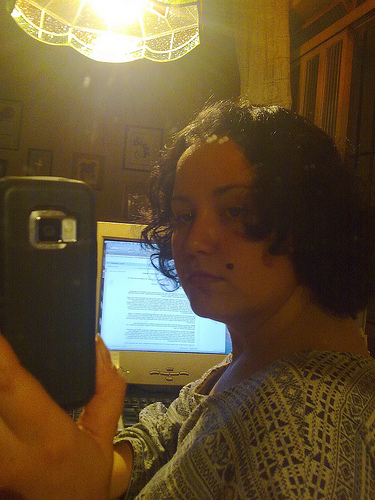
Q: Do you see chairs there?
A: No, there are no chairs.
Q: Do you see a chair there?
A: No, there are no chairs.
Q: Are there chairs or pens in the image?
A: No, there are no chairs or pens.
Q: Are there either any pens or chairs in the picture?
A: No, there are no chairs or pens.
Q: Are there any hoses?
A: No, there are no hoses.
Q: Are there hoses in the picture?
A: No, there are no hoses.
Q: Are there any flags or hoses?
A: No, there are no hoses or flags.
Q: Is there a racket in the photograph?
A: No, there are no rackets.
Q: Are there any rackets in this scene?
A: No, there are no rackets.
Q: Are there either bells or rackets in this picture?
A: No, there are no rackets or bells.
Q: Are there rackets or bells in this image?
A: No, there are no rackets or bells.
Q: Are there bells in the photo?
A: No, there are no bells.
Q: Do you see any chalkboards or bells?
A: No, there are no bells or chalkboards.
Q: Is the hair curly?
A: Yes, the hair is curly.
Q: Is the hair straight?
A: No, the hair is curly.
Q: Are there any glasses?
A: No, there are no glasses.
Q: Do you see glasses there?
A: No, there are no glasses.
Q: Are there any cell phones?
A: Yes, there is a cell phone.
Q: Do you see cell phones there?
A: Yes, there is a cell phone.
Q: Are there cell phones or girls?
A: Yes, there is a cell phone.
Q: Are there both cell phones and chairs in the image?
A: No, there is a cell phone but no chairs.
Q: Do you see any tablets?
A: No, there are no tablets.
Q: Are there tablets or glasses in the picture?
A: No, there are no tablets or glasses.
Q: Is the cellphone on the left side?
A: Yes, the cellphone is on the left of the image.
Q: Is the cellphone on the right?
A: No, the cellphone is on the left of the image.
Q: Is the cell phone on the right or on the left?
A: The cell phone is on the left of the image.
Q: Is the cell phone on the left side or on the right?
A: The cell phone is on the left of the image.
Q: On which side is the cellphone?
A: The cellphone is on the left of the image.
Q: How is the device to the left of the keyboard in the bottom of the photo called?
A: The device is a cell phone.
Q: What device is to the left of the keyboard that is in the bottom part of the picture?
A: The device is a cell phone.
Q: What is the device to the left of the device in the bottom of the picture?
A: The device is a cell phone.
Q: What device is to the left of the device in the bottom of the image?
A: The device is a cell phone.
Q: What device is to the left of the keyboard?
A: The device is a cell phone.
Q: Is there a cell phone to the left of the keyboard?
A: Yes, there is a cell phone to the left of the keyboard.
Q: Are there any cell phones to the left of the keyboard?
A: Yes, there is a cell phone to the left of the keyboard.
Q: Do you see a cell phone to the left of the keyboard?
A: Yes, there is a cell phone to the left of the keyboard.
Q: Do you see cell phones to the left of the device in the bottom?
A: Yes, there is a cell phone to the left of the keyboard.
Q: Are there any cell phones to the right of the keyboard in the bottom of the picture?
A: No, the cell phone is to the left of the keyboard.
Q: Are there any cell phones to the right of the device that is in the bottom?
A: No, the cell phone is to the left of the keyboard.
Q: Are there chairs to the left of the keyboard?
A: No, there is a cell phone to the left of the keyboard.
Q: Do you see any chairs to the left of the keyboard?
A: No, there is a cell phone to the left of the keyboard.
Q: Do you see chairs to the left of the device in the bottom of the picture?
A: No, there is a cell phone to the left of the keyboard.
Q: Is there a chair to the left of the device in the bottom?
A: No, there is a cell phone to the left of the keyboard.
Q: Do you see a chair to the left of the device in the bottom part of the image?
A: No, there is a cell phone to the left of the keyboard.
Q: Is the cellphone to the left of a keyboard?
A: Yes, the cellphone is to the left of a keyboard.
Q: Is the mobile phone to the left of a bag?
A: No, the mobile phone is to the left of a keyboard.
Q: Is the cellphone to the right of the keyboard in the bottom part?
A: No, the cellphone is to the left of the keyboard.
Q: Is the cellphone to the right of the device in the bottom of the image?
A: No, the cellphone is to the left of the keyboard.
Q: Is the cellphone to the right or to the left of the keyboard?
A: The cellphone is to the left of the keyboard.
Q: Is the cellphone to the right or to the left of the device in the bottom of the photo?
A: The cellphone is to the left of the keyboard.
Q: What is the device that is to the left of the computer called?
A: The device is a cell phone.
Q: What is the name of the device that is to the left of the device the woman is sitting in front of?
A: The device is a cell phone.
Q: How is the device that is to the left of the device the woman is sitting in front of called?
A: The device is a cell phone.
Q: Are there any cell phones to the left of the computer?
A: Yes, there is a cell phone to the left of the computer.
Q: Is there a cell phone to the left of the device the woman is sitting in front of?
A: Yes, there is a cell phone to the left of the computer.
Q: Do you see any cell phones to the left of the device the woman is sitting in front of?
A: Yes, there is a cell phone to the left of the computer.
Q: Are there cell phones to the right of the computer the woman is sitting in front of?
A: No, the cell phone is to the left of the computer.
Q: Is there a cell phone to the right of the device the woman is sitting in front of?
A: No, the cell phone is to the left of the computer.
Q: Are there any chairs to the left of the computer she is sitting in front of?
A: No, there is a cell phone to the left of the computer.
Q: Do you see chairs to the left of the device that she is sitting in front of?
A: No, there is a cell phone to the left of the computer.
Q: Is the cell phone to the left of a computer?
A: Yes, the cell phone is to the left of a computer.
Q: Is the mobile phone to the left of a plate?
A: No, the mobile phone is to the left of a computer.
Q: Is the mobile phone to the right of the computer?
A: No, the mobile phone is to the left of the computer.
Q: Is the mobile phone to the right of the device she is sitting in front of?
A: No, the mobile phone is to the left of the computer.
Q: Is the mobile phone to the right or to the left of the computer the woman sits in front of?
A: The mobile phone is to the left of the computer.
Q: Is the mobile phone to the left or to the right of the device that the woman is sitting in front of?
A: The mobile phone is to the left of the computer.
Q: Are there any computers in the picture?
A: Yes, there is a computer.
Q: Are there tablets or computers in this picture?
A: Yes, there is a computer.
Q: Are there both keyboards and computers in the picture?
A: Yes, there are both a computer and a keyboard.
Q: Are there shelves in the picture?
A: No, there are no shelves.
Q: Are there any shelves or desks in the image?
A: No, there are no shelves or desks.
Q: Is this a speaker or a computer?
A: This is a computer.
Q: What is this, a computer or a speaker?
A: This is a computer.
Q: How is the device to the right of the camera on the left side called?
A: The device is a computer.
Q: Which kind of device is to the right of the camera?
A: The device is a computer.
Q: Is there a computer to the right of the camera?
A: Yes, there is a computer to the right of the camera.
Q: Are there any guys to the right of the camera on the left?
A: No, there is a computer to the right of the camera.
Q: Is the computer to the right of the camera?
A: Yes, the computer is to the right of the camera.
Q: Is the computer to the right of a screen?
A: No, the computer is to the right of the camera.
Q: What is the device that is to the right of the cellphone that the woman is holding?
A: The device is a computer.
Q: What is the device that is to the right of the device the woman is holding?
A: The device is a computer.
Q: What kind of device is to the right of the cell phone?
A: The device is a computer.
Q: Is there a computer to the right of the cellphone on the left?
A: Yes, there is a computer to the right of the cellphone.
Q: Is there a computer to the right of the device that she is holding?
A: Yes, there is a computer to the right of the cellphone.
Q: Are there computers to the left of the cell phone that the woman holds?
A: No, the computer is to the right of the cellphone.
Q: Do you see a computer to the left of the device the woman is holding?
A: No, the computer is to the right of the cellphone.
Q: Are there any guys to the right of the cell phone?
A: No, there is a computer to the right of the cell phone.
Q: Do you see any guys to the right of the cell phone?
A: No, there is a computer to the right of the cell phone.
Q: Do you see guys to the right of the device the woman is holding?
A: No, there is a computer to the right of the cell phone.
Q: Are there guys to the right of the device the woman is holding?
A: No, there is a computer to the right of the cell phone.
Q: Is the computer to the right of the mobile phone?
A: Yes, the computer is to the right of the mobile phone.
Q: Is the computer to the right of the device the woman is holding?
A: Yes, the computer is to the right of the mobile phone.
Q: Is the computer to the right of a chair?
A: No, the computer is to the right of the mobile phone.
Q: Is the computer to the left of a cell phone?
A: No, the computer is to the right of a cell phone.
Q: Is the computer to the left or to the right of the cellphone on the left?
A: The computer is to the right of the mobile phone.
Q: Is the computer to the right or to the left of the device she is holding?
A: The computer is to the right of the mobile phone.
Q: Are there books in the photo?
A: No, there are no books.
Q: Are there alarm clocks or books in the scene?
A: No, there are no books or alarm clocks.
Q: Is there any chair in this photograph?
A: No, there are no chairs.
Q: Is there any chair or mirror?
A: No, there are no chairs or mirrors.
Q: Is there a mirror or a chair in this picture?
A: No, there are no chairs or mirrors.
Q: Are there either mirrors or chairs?
A: No, there are no chairs or mirrors.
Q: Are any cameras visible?
A: Yes, there is a camera.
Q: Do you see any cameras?
A: Yes, there is a camera.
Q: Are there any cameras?
A: Yes, there is a camera.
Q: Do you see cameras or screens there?
A: Yes, there is a camera.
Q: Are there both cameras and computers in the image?
A: Yes, there are both a camera and a computer.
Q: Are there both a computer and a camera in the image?
A: Yes, there are both a camera and a computer.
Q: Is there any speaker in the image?
A: No, there are no speakers.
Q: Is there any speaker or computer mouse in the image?
A: No, there are no speakers or computer mice.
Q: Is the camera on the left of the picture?
A: Yes, the camera is on the left of the image.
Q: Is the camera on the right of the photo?
A: No, the camera is on the left of the image.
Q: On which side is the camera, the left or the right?
A: The camera is on the left of the image.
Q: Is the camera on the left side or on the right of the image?
A: The camera is on the left of the image.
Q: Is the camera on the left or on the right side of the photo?
A: The camera is on the left of the image.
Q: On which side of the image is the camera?
A: The camera is on the left of the image.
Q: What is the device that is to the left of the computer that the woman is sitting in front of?
A: The device is a camera.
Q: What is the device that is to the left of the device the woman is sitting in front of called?
A: The device is a camera.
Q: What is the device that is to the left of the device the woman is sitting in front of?
A: The device is a camera.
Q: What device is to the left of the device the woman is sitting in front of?
A: The device is a camera.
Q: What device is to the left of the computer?
A: The device is a camera.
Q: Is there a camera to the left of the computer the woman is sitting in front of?
A: Yes, there is a camera to the left of the computer.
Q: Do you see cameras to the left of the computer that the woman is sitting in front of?
A: Yes, there is a camera to the left of the computer.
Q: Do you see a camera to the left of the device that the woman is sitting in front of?
A: Yes, there is a camera to the left of the computer.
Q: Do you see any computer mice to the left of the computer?
A: No, there is a camera to the left of the computer.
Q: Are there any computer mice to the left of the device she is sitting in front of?
A: No, there is a camera to the left of the computer.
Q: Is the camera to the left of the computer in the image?
A: Yes, the camera is to the left of the computer.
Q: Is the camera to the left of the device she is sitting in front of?
A: Yes, the camera is to the left of the computer.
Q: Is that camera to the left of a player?
A: No, the camera is to the left of the computer.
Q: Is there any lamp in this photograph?
A: Yes, there is a lamp.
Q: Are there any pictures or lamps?
A: Yes, there is a lamp.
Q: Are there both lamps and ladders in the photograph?
A: No, there is a lamp but no ladders.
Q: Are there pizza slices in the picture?
A: No, there are no pizza slices.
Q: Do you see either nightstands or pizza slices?
A: No, there are no pizza slices or nightstands.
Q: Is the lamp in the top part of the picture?
A: Yes, the lamp is in the top of the image.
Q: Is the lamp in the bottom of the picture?
A: No, the lamp is in the top of the image.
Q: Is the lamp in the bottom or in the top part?
A: The lamp is in the top of the image.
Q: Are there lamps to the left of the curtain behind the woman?
A: Yes, there is a lamp to the left of the curtain.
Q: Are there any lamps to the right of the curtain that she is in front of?
A: No, the lamp is to the left of the curtain.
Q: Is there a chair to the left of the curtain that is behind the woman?
A: No, there is a lamp to the left of the curtain.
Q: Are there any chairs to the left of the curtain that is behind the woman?
A: No, there is a lamp to the left of the curtain.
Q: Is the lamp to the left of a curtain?
A: Yes, the lamp is to the left of a curtain.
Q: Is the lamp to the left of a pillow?
A: No, the lamp is to the left of a curtain.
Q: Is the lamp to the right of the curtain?
A: No, the lamp is to the left of the curtain.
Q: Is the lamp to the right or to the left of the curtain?
A: The lamp is to the left of the curtain.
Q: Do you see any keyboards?
A: Yes, there is a keyboard.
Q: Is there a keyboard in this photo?
A: Yes, there is a keyboard.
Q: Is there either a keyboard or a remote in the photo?
A: Yes, there is a keyboard.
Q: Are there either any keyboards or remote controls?
A: Yes, there is a keyboard.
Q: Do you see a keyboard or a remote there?
A: Yes, there is a keyboard.